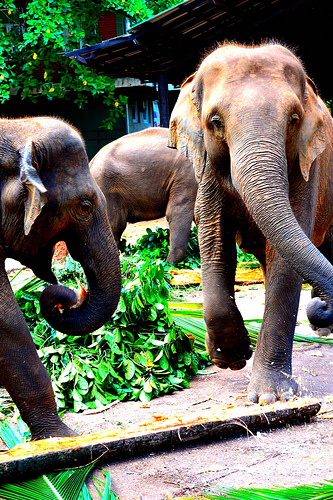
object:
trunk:
[39, 216, 123, 338]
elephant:
[0, 110, 122, 442]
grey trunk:
[227, 105, 332, 326]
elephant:
[168, 41, 332, 406]